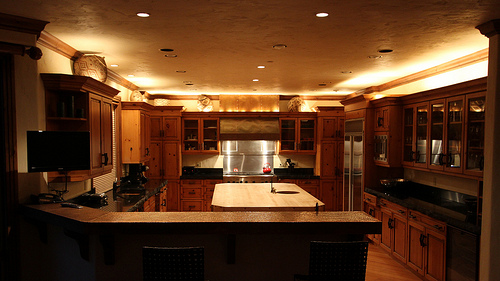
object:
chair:
[142, 246, 207, 281]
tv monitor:
[25, 129, 93, 172]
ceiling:
[11, 0, 493, 96]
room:
[0, 0, 499, 281]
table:
[208, 182, 328, 210]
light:
[110, 64, 123, 69]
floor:
[364, 243, 419, 281]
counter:
[21, 200, 383, 235]